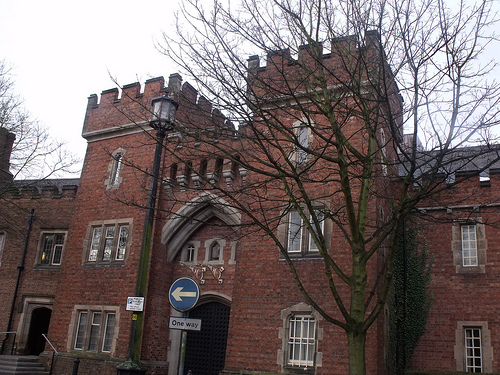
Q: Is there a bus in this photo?
A: No, there are no buses.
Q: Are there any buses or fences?
A: No, there are no buses or fences.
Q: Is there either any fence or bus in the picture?
A: No, there are no buses or fences.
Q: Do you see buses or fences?
A: No, there are no buses or fences.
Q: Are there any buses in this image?
A: No, there are no buses.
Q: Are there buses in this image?
A: No, there are no buses.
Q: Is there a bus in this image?
A: No, there are no buses.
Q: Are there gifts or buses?
A: No, there are no buses or gifts.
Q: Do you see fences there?
A: No, there are no fences.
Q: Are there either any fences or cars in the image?
A: No, there are no fences or cars.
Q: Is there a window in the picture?
A: Yes, there is a window.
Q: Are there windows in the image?
A: Yes, there is a window.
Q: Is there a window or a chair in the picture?
A: Yes, there is a window.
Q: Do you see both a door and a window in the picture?
A: Yes, there are both a window and a door.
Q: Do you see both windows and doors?
A: Yes, there are both a window and a door.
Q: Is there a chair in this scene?
A: No, there are no chairs.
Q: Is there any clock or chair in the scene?
A: No, there are no chairs or clocks.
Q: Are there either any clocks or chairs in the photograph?
A: No, there are no chairs or clocks.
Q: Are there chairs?
A: No, there are no chairs.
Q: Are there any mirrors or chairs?
A: No, there are no chairs or mirrors.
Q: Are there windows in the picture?
A: Yes, there is a window.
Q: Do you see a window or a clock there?
A: Yes, there is a window.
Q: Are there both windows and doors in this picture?
A: Yes, there are both a window and a door.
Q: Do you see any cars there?
A: No, there are no cars.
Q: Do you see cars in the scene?
A: No, there are no cars.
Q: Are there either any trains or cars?
A: No, there are no cars or trains.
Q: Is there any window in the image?
A: Yes, there is a window.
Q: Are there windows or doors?
A: Yes, there is a window.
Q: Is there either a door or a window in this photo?
A: Yes, there is a window.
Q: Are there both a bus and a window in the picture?
A: No, there is a window but no buses.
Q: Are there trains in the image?
A: No, there are no trains.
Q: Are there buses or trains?
A: No, there are no trains or buses.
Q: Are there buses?
A: No, there are no buses.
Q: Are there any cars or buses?
A: No, there are no buses or cars.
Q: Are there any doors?
A: Yes, there is a door.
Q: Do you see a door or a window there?
A: Yes, there is a door.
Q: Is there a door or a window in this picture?
A: Yes, there is a door.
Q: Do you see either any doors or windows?
A: Yes, there is a door.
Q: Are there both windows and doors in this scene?
A: Yes, there are both a door and a window.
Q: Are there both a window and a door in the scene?
A: Yes, there are both a door and a window.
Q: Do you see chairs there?
A: No, there are no chairs.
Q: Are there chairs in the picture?
A: No, there are no chairs.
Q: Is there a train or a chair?
A: No, there are no chairs or trains.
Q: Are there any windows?
A: Yes, there is a window.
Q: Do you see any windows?
A: Yes, there is a window.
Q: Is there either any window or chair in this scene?
A: Yes, there is a window.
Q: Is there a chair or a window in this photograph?
A: Yes, there is a window.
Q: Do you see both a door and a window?
A: Yes, there are both a window and a door.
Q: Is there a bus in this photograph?
A: No, there are no buses.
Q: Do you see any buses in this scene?
A: No, there are no buses.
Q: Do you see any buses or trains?
A: No, there are no buses or trains.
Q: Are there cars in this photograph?
A: No, there are no cars.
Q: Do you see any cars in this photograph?
A: No, there are no cars.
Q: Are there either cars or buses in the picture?
A: No, there are no cars or buses.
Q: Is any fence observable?
A: No, there are no fences.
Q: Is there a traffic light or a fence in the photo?
A: No, there are no fences or traffic lights.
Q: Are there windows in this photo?
A: Yes, there is a window.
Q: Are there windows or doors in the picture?
A: Yes, there is a window.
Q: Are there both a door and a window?
A: Yes, there are both a window and a door.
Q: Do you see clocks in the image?
A: No, there are no clocks.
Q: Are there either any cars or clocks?
A: No, there are no clocks or cars.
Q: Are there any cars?
A: No, there are no cars.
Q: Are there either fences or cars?
A: No, there are no cars or fences.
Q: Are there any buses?
A: No, there are no buses.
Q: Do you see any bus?
A: No, there are no buses.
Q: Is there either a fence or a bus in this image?
A: No, there are no buses or fences.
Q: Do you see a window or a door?
A: Yes, there is a window.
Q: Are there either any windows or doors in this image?
A: Yes, there is a window.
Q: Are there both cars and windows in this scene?
A: No, there is a window but no cars.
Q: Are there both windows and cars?
A: No, there is a window but no cars.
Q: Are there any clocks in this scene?
A: No, there are no clocks.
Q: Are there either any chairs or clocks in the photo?
A: No, there are no clocks or chairs.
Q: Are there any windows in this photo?
A: Yes, there is a window.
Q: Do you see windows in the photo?
A: Yes, there is a window.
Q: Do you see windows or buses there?
A: Yes, there is a window.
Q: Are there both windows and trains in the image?
A: No, there is a window but no trains.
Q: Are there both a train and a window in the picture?
A: No, there is a window but no trains.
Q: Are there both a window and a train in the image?
A: No, there is a window but no trains.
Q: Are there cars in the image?
A: No, there are no cars.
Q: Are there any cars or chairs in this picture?
A: No, there are no cars or chairs.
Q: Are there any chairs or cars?
A: No, there are no cars or chairs.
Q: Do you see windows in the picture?
A: Yes, there is a window.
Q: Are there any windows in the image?
A: Yes, there is a window.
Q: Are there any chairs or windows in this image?
A: Yes, there is a window.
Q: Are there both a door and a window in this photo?
A: Yes, there are both a window and a door.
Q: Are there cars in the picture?
A: No, there are no cars.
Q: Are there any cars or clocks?
A: No, there are no cars or clocks.